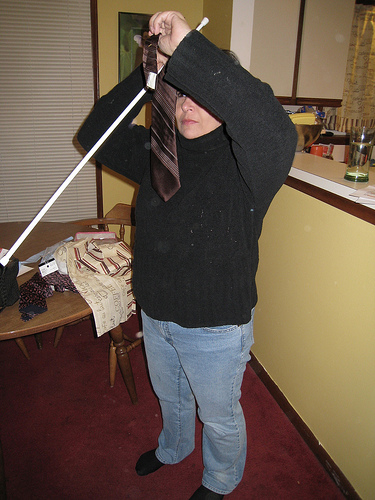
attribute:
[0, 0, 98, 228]
blinds — white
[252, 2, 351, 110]
cupboard — storing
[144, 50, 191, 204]
tie — brown, stripped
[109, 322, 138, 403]
leg — brown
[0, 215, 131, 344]
table — messy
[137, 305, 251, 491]
jeans — blue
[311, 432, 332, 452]
white spot — small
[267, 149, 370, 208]
bar — between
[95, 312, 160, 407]
peg — wooden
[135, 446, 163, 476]
sock — black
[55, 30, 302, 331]
sweater — thick, black